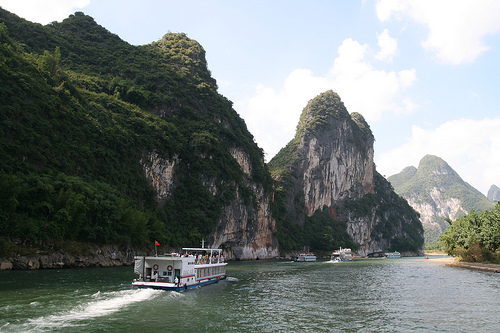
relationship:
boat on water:
[129, 236, 227, 296] [322, 264, 400, 312]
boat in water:
[129, 236, 227, 296] [322, 264, 400, 312]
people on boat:
[197, 251, 224, 265] [129, 236, 227, 296]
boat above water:
[129, 236, 227, 296] [322, 264, 400, 312]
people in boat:
[197, 251, 224, 265] [129, 236, 227, 296]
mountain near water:
[101, 44, 292, 222] [322, 264, 400, 312]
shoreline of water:
[5, 239, 292, 279] [0, 254, 500, 326]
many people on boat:
[141, 249, 233, 292] [129, 236, 227, 296]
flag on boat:
[156, 234, 162, 247] [133, 242, 235, 291]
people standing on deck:
[187, 248, 225, 261] [182, 242, 233, 288]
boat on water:
[136, 229, 227, 289] [2, 250, 495, 330]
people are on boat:
[187, 249, 227, 264] [128, 237, 229, 295]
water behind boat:
[40, 276, 164, 326] [130, 234, 224, 288]